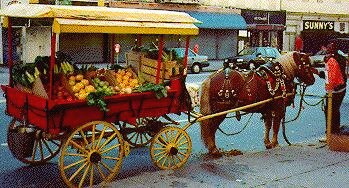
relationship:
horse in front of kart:
[200, 50, 317, 158] [1, 4, 205, 186]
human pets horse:
[306, 39, 346, 132] [200, 50, 317, 158]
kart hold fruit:
[1, 4, 205, 186] [118, 65, 133, 84]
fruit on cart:
[111, 70, 135, 99] [45, 95, 172, 122]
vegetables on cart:
[14, 43, 187, 106] [3, 2, 201, 180]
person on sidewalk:
[319, 46, 348, 144] [82, 128, 347, 187]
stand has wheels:
[2, 0, 203, 184] [54, 115, 196, 186]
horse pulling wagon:
[192, 50, 310, 158] [3, 3, 208, 181]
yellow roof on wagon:
[3, 2, 200, 36] [3, 3, 208, 181]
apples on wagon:
[82, 79, 114, 94] [3, 3, 208, 181]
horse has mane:
[192, 50, 310, 158] [271, 49, 299, 82]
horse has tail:
[192, 50, 310, 158] [197, 76, 213, 148]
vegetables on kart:
[18, 59, 155, 100] [16, 20, 204, 183]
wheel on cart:
[150, 130, 195, 165] [7, 0, 194, 124]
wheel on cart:
[56, 118, 125, 185] [3, 2, 201, 180]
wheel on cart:
[149, 123, 190, 169] [3, 2, 201, 180]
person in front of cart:
[309, 41, 345, 135] [3, 2, 201, 180]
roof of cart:
[3, 3, 195, 32] [29, 34, 200, 173]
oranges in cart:
[107, 67, 146, 95] [3, 2, 201, 180]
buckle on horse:
[252, 58, 288, 82] [200, 50, 317, 158]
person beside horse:
[318, 41, 345, 142] [200, 50, 317, 158]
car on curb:
[168, 45, 210, 73] [204, 67, 222, 73]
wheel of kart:
[64, 123, 124, 187] [1, 2, 205, 186]